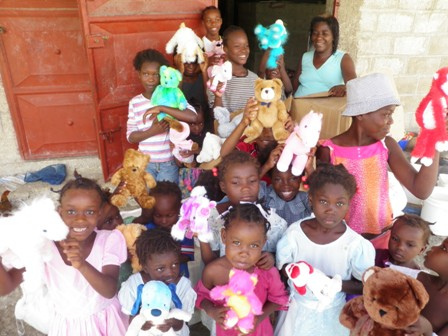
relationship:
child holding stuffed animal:
[117, 227, 198, 336] [123, 280, 194, 336]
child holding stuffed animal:
[274, 162, 378, 336] [284, 259, 344, 313]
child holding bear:
[194, 203, 290, 336] [206, 266, 259, 335]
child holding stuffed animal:
[194, 203, 290, 336] [276, 110, 323, 176]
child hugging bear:
[125, 48, 198, 182] [148, 58, 188, 123]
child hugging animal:
[125, 48, 198, 182] [150, 65, 187, 122]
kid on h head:
[220, 94, 294, 186] [256, 126, 276, 149]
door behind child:
[7, 3, 257, 149] [0, 168, 128, 336]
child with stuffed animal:
[26, 170, 127, 334] [339, 266, 434, 335]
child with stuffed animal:
[117, 227, 198, 333] [284, 259, 345, 312]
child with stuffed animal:
[195, 195, 287, 333] [208, 265, 263, 334]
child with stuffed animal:
[274, 160, 378, 334] [123, 280, 194, 334]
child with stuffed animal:
[124, 46, 200, 184] [275, 109, 323, 175]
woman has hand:
[294, 12, 340, 83] [329, 79, 346, 100]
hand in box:
[329, 79, 346, 100] [300, 90, 344, 138]